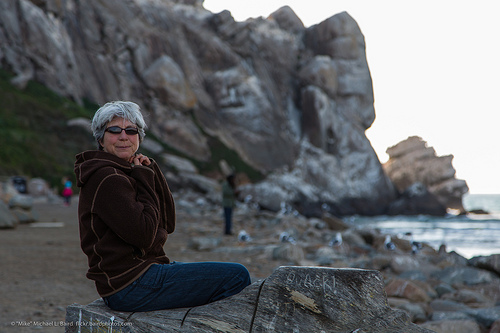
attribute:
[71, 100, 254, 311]
woman — sitting down, sitting outside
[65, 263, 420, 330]
rock — large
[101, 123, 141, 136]
sunglasses — black, dark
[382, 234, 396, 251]
seagull — standing in distance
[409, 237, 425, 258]
seagull — standing in distance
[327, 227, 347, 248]
seagull — standing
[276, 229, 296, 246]
seagull — standing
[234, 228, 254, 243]
seagull — standing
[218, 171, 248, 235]
person — standing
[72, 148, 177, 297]
hoodie — brown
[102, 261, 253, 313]
pair of jeans — blue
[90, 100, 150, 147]
hair — gray, peppered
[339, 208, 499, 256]
water — calm